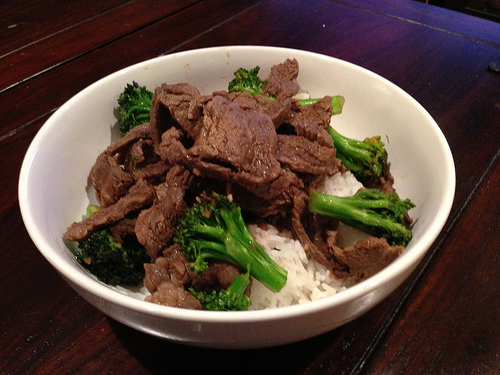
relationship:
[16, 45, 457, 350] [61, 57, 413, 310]
bowl with eatables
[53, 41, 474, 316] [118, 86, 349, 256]
bowl with food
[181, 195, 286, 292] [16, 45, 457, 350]
broccoli on bowl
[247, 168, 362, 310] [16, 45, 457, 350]
rice on bowl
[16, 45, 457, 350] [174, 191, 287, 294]
bowl with broccoli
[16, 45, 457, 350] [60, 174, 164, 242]
bowl with beef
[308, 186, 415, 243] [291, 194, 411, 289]
broccoli on top of beef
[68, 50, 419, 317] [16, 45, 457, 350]
meal on bowl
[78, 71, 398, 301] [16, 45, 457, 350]
meal on bowl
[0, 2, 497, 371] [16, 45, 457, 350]
table with bowl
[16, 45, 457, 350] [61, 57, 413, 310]
bowl of eatables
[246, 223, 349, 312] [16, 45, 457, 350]
rice in bowl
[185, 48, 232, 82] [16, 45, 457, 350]
juice in bowl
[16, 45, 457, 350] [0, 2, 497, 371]
bowl on table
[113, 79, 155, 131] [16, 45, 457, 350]
broccoli on bowl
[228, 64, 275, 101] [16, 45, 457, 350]
broccoli on bowl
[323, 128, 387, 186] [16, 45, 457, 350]
broccoli on bowl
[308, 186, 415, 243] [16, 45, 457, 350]
broccoli on bowl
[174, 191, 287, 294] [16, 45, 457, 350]
broccoli on bowl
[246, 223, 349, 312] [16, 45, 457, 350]
rice on bowl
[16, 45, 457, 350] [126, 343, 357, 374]
bowl has shadow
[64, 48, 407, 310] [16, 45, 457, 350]
eatables in bowl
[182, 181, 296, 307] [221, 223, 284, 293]
broccoli has stem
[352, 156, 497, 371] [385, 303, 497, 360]
crack between board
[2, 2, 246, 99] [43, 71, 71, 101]
crack between board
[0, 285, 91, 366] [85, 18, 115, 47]
crack between board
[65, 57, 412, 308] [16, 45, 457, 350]
steak in bowl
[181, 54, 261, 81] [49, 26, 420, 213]
sauce on bowl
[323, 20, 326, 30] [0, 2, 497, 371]
spot on table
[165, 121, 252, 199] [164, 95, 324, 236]
slice of beef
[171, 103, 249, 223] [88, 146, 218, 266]
slice of beef